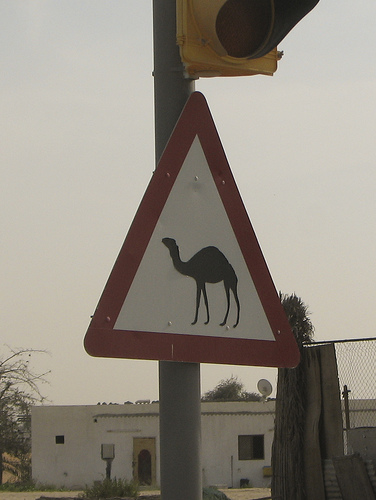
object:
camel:
[160, 235, 242, 330]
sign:
[82, 90, 304, 373]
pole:
[150, 2, 205, 500]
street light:
[174, 1, 320, 81]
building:
[29, 398, 376, 490]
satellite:
[257, 378, 274, 402]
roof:
[31, 398, 374, 416]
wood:
[269, 345, 326, 500]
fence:
[272, 337, 376, 500]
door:
[133, 436, 157, 491]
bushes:
[79, 475, 141, 500]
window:
[237, 434, 265, 462]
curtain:
[239, 435, 254, 460]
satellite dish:
[257, 378, 273, 396]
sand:
[217, 488, 270, 500]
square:
[55, 434, 64, 444]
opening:
[56, 434, 65, 444]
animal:
[239, 478, 249, 489]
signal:
[201, 0, 319, 66]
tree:
[0, 346, 56, 493]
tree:
[275, 291, 315, 352]